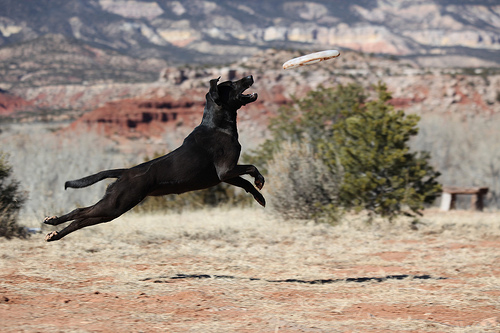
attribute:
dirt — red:
[2, 231, 499, 331]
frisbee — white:
[281, 49, 338, 68]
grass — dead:
[1, 214, 497, 331]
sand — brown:
[22, 246, 499, 331]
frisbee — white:
[280, 43, 341, 75]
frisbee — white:
[275, 31, 356, 80]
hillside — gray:
[0, 0, 499, 72]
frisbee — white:
[278, 47, 350, 85]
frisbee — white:
[275, 44, 343, 72]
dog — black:
[35, 69, 282, 251]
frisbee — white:
[283, 45, 340, 70]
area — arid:
[6, 189, 493, 331]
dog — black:
[42, 73, 267, 240]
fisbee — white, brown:
[274, 44, 348, 80]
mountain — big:
[22, 6, 497, 58]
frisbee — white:
[261, 40, 356, 77]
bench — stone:
[422, 139, 497, 226]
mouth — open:
[220, 70, 265, 108]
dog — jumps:
[44, 67, 273, 255]